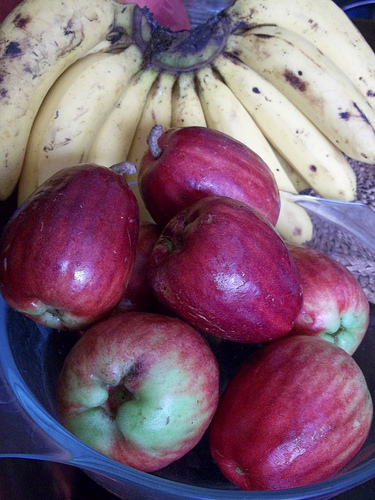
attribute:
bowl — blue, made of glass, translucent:
[2, 193, 375, 499]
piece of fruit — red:
[153, 196, 305, 348]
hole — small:
[98, 381, 135, 416]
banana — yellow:
[226, 34, 373, 169]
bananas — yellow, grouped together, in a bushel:
[2, 3, 372, 244]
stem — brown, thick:
[132, 3, 230, 73]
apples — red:
[0, 120, 374, 495]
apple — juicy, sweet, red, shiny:
[208, 335, 374, 491]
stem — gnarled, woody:
[147, 121, 163, 155]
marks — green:
[61, 354, 208, 467]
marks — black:
[276, 66, 374, 140]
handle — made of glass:
[1, 365, 70, 463]